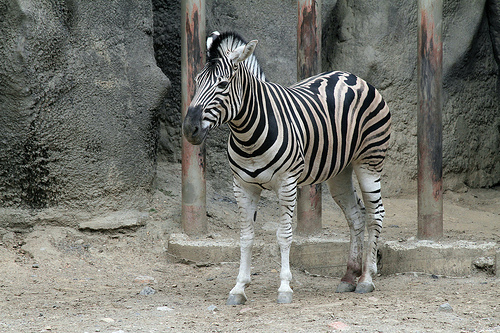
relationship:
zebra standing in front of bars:
[181, 28, 407, 294] [158, 0, 498, 265]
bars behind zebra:
[158, 0, 498, 265] [181, 28, 407, 294]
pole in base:
[175, 1, 217, 239] [161, 224, 500, 274]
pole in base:
[296, 0, 330, 235] [161, 224, 500, 274]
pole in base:
[415, 1, 449, 238] [161, 224, 500, 274]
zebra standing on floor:
[181, 28, 407, 294] [6, 182, 499, 325]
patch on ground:
[307, 187, 500, 232] [6, 189, 500, 327]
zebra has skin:
[181, 28, 407, 294] [204, 72, 394, 260]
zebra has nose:
[181, 28, 407, 294] [182, 111, 205, 144]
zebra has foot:
[181, 28, 407, 294] [275, 289, 294, 308]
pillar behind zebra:
[179, 0, 210, 231] [181, 28, 407, 294]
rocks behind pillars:
[5, 0, 493, 223] [173, 0, 459, 231]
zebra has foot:
[181, 28, 407, 294] [227, 293, 247, 308]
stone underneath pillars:
[160, 238, 500, 264] [177, 6, 449, 240]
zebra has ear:
[181, 28, 407, 294] [227, 39, 263, 66]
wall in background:
[7, 4, 497, 274] [9, 5, 500, 277]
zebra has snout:
[181, 28, 407, 294] [181, 106, 207, 147]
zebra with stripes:
[181, 28, 407, 294] [202, 75, 382, 191]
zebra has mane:
[181, 28, 407, 294] [206, 29, 273, 83]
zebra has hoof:
[181, 28, 407, 294] [277, 287, 296, 311]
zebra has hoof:
[181, 28, 407, 294] [229, 292, 246, 305]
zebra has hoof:
[181, 28, 407, 294] [356, 280, 378, 294]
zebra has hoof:
[181, 28, 407, 294] [335, 279, 355, 294]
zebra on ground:
[181, 28, 407, 294] [6, 189, 500, 327]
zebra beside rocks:
[181, 28, 407, 294] [5, 0, 493, 223]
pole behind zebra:
[296, 0, 330, 235] [181, 28, 407, 294]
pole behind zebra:
[183, 3, 212, 238] [181, 28, 407, 294]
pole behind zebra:
[415, 1, 449, 238] [181, 28, 407, 294]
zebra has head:
[181, 28, 407, 294] [184, 25, 265, 146]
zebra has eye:
[181, 28, 407, 294] [217, 80, 236, 90]